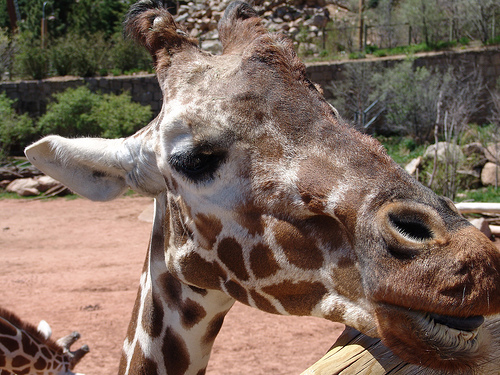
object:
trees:
[402, 62, 491, 148]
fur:
[116, 194, 380, 371]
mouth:
[366, 287, 499, 351]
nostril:
[380, 201, 446, 249]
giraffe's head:
[24, 4, 499, 370]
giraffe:
[23, 0, 498, 374]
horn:
[124, 0, 213, 80]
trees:
[36, 85, 152, 139]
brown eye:
[165, 140, 229, 190]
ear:
[21, 133, 157, 201]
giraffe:
[1, 307, 91, 374]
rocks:
[423, 140, 467, 168]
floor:
[5, 201, 137, 316]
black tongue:
[434, 315, 486, 329]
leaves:
[435, 77, 459, 98]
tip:
[137, 7, 167, 32]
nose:
[361, 175, 497, 265]